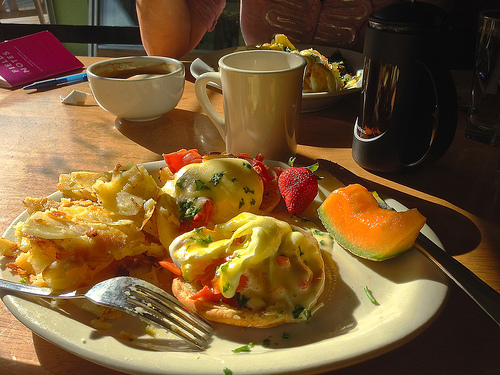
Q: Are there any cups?
A: Yes, there is a cup.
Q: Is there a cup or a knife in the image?
A: Yes, there is a cup.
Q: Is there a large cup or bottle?
A: Yes, there is a large cup.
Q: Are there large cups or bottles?
A: Yes, there is a large cup.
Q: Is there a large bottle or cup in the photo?
A: Yes, there is a large cup.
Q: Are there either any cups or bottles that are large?
A: Yes, the cup is large.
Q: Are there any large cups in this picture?
A: Yes, there is a large cup.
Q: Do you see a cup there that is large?
A: Yes, there is a cup that is large.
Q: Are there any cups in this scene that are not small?
A: Yes, there is a large cup.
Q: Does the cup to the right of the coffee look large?
A: Yes, the cup is large.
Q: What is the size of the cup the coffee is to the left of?
A: The cup is large.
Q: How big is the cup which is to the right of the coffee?
A: The cup is large.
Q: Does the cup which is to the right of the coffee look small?
A: No, the cup is large.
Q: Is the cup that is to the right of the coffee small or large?
A: The cup is large.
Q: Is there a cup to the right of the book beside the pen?
A: Yes, there is a cup to the right of the book.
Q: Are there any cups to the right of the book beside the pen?
A: Yes, there is a cup to the right of the book.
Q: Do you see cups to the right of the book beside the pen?
A: Yes, there is a cup to the right of the book.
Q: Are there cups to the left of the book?
A: No, the cup is to the right of the book.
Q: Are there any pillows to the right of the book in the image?
A: No, there is a cup to the right of the book.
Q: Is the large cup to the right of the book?
A: Yes, the cup is to the right of the book.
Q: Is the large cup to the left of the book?
A: No, the cup is to the right of the book.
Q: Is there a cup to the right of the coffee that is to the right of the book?
A: Yes, there is a cup to the right of the coffee.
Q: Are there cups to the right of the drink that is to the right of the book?
A: Yes, there is a cup to the right of the coffee.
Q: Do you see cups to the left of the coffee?
A: No, the cup is to the right of the coffee.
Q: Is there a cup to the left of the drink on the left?
A: No, the cup is to the right of the coffee.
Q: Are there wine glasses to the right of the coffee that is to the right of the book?
A: No, there is a cup to the right of the coffee.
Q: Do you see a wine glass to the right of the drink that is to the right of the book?
A: No, there is a cup to the right of the coffee.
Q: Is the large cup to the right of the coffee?
A: Yes, the cup is to the right of the coffee.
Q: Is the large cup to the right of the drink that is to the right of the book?
A: Yes, the cup is to the right of the coffee.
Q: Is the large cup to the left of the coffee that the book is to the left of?
A: No, the cup is to the right of the coffee.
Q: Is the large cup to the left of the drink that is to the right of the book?
A: No, the cup is to the right of the coffee.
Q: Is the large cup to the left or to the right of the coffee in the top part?
A: The cup is to the right of the coffee.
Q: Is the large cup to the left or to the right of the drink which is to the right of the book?
A: The cup is to the right of the coffee.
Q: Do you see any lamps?
A: No, there are no lamps.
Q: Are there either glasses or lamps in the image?
A: No, there are no lamps or glasses.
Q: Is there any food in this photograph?
A: Yes, there is food.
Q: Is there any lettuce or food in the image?
A: Yes, there is food.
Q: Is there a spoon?
A: No, there are no spoons.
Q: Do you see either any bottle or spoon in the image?
A: No, there are no spoons or bottles.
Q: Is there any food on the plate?
A: Yes, there is food on the plate.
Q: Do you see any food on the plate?
A: Yes, there is food on the plate.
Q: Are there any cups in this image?
A: Yes, there is a cup.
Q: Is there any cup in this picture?
A: Yes, there is a cup.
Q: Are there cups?
A: Yes, there is a cup.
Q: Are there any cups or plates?
A: Yes, there is a cup.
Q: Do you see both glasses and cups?
A: No, there is a cup but no glasses.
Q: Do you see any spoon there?
A: No, there are no spoons.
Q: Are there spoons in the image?
A: No, there are no spoons.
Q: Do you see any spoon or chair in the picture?
A: No, there are no spoons or chairs.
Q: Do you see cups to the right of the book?
A: Yes, there is a cup to the right of the book.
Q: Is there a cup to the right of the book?
A: Yes, there is a cup to the right of the book.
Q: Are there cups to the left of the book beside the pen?
A: No, the cup is to the right of the book.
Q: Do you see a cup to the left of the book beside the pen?
A: No, the cup is to the right of the book.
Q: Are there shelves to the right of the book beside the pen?
A: No, there is a cup to the right of the book.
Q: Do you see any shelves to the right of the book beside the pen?
A: No, there is a cup to the right of the book.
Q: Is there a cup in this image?
A: Yes, there is a cup.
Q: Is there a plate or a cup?
A: Yes, there is a cup.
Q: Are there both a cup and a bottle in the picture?
A: No, there is a cup but no bottles.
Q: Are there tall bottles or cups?
A: Yes, there is a tall cup.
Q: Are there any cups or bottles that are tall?
A: Yes, the cup is tall.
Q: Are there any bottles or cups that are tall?
A: Yes, the cup is tall.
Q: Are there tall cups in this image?
A: Yes, there is a tall cup.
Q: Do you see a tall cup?
A: Yes, there is a tall cup.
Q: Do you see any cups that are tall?
A: Yes, there is a cup that is tall.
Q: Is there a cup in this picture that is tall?
A: Yes, there is a cup that is tall.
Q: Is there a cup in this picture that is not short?
A: Yes, there is a tall cup.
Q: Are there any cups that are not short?
A: Yes, there is a tall cup.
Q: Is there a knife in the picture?
A: Yes, there is a knife.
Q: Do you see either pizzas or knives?
A: Yes, there is a knife.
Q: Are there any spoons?
A: No, there are no spoons.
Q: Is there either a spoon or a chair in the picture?
A: No, there are no spoons or chairs.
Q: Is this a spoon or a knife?
A: This is a knife.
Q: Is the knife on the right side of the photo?
A: Yes, the knife is on the right of the image.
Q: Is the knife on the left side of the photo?
A: No, the knife is on the right of the image.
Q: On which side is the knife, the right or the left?
A: The knife is on the right of the image.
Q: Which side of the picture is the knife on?
A: The knife is on the right of the image.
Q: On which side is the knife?
A: The knife is on the right of the image.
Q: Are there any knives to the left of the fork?
A: No, the knife is to the right of the fork.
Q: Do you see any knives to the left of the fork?
A: No, the knife is to the right of the fork.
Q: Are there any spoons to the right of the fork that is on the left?
A: No, there is a knife to the right of the fork.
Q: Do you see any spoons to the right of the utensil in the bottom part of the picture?
A: No, there is a knife to the right of the fork.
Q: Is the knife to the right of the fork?
A: Yes, the knife is to the right of the fork.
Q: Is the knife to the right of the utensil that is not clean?
A: Yes, the knife is to the right of the fork.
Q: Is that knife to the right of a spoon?
A: No, the knife is to the right of the fork.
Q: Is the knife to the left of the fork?
A: No, the knife is to the right of the fork.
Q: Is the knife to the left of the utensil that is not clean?
A: No, the knife is to the right of the fork.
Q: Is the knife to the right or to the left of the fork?
A: The knife is to the right of the fork.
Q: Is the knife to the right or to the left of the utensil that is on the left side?
A: The knife is to the right of the fork.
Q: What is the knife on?
A: The knife is on the plate.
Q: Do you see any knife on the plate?
A: Yes, there is a knife on the plate.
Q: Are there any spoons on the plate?
A: No, there is a knife on the plate.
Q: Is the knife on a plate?
A: Yes, the knife is on a plate.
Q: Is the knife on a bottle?
A: No, the knife is on a plate.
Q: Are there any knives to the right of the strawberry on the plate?
A: Yes, there is a knife to the right of the strawberry.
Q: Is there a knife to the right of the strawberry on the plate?
A: Yes, there is a knife to the right of the strawberry.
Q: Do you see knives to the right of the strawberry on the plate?
A: Yes, there is a knife to the right of the strawberry.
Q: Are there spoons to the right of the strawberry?
A: No, there is a knife to the right of the strawberry.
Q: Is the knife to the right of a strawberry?
A: Yes, the knife is to the right of a strawberry.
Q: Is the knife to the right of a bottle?
A: No, the knife is to the right of a strawberry.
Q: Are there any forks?
A: Yes, there is a fork.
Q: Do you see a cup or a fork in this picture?
A: Yes, there is a fork.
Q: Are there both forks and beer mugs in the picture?
A: No, there is a fork but no beer mugs.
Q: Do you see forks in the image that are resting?
A: Yes, there is a fork that is resting.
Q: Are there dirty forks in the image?
A: Yes, there is a dirty fork.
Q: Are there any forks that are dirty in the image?
A: Yes, there is a dirty fork.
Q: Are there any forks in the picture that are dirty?
A: Yes, there is a fork that is dirty.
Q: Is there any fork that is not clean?
A: Yes, there is a dirty fork.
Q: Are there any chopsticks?
A: No, there are no chopsticks.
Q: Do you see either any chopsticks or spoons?
A: No, there are no chopsticks or spoons.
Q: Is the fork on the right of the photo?
A: No, the fork is on the left of the image.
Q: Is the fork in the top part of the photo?
A: No, the fork is in the bottom of the image.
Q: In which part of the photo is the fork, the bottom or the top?
A: The fork is in the bottom of the image.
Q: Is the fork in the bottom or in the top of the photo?
A: The fork is in the bottom of the image.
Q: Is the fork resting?
A: Yes, the fork is resting.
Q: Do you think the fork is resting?
A: Yes, the fork is resting.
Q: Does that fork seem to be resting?
A: Yes, the fork is resting.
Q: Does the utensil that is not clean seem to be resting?
A: Yes, the fork is resting.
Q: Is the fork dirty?
A: Yes, the fork is dirty.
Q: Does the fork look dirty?
A: Yes, the fork is dirty.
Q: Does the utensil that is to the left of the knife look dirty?
A: Yes, the fork is dirty.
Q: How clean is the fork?
A: The fork is dirty.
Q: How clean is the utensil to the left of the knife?
A: The fork is dirty.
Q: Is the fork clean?
A: No, the fork is dirty.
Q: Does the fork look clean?
A: No, the fork is dirty.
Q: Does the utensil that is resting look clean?
A: No, the fork is dirty.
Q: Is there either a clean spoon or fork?
A: No, there is a fork but it is dirty.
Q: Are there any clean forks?
A: No, there is a fork but it is dirty.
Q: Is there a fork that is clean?
A: No, there is a fork but it is dirty.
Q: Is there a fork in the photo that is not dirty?
A: No, there is a fork but it is dirty.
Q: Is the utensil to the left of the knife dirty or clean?
A: The fork is dirty.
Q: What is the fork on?
A: The fork is on the plate.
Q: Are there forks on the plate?
A: Yes, there is a fork on the plate.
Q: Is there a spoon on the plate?
A: No, there is a fork on the plate.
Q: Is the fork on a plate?
A: Yes, the fork is on a plate.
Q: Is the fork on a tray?
A: No, the fork is on a plate.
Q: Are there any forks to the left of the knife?
A: Yes, there is a fork to the left of the knife.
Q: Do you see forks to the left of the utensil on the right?
A: Yes, there is a fork to the left of the knife.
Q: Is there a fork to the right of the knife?
A: No, the fork is to the left of the knife.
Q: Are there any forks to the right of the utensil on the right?
A: No, the fork is to the left of the knife.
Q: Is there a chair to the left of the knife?
A: No, there is a fork to the left of the knife.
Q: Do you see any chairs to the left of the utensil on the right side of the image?
A: No, there is a fork to the left of the knife.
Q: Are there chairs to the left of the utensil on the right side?
A: No, there is a fork to the left of the knife.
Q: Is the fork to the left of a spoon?
A: No, the fork is to the left of a knife.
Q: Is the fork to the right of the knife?
A: No, the fork is to the left of the knife.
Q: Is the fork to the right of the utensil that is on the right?
A: No, the fork is to the left of the knife.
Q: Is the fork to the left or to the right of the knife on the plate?
A: The fork is to the left of the knife.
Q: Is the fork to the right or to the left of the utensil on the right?
A: The fork is to the left of the knife.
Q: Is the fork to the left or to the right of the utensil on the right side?
A: The fork is to the left of the knife.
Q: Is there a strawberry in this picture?
A: Yes, there is a strawberry.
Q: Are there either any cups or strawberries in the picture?
A: Yes, there is a strawberry.